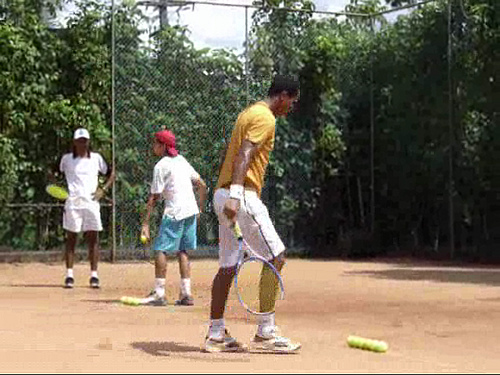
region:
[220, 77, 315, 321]
a man holding a tennis racket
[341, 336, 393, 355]
a row of tennis balls on the ground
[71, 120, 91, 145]
a man wearing a white hat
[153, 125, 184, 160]
a man wearing a white hat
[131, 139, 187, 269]
a man holding a tennis ball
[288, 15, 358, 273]
a tall chain link fence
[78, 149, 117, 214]
a man with his hand on his hip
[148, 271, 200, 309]
a man wearing white socks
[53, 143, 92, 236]
a man holding a yellow tennis racket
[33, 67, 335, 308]
three men on a tennis court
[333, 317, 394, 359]
Tennis balls lined up in a row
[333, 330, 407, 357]
The tennis balls are yellow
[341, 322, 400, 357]
There are 6 tennis balls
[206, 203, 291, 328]
Man is holding a tennis racket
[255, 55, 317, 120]
The man has dark hair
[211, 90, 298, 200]
Man is wearing a yellow T shirt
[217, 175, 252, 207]
Man is wearing a white wrist band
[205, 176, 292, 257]
Man is wearing white shorts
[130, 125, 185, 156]
Man is wearing a red cap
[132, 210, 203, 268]
Man is wearing blue shorts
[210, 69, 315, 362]
A man playing tennis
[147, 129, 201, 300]
A man playing tennis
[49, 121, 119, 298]
A man playing tennis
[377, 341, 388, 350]
A small yellow tennis ball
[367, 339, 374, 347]
A small yellow tennis ball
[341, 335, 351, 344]
A small yellow tennis ball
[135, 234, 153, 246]
A small yellow tennis ball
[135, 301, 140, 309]
A small yellow tennis ball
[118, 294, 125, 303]
A small yellow tennis ball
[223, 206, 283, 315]
A yellow handle tennis racket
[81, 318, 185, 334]
red clay tennis court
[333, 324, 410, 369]
row of yellow tennis balls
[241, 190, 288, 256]
black stripe at side of shorts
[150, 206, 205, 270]
blue tennis shorts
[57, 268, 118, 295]
black and white sneakers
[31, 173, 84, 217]
yellow tennis racket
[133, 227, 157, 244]
tennis ball in man's hand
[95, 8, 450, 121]
tall silver chain link fence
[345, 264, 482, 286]
tree's shadow on court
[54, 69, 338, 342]
players on the tennis court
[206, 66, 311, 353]
man wearing yellow shirt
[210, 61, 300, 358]
man wearing white shorts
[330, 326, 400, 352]
balls on tennis court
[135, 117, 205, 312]
boy wearing a cap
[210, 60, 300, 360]
man holding a tennis racket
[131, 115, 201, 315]
boy wearing white shirt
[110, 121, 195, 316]
boy wearing blue shorts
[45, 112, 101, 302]
man wearing white shirt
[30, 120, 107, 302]
man wearing white shorts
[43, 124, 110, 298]
man holding a racket